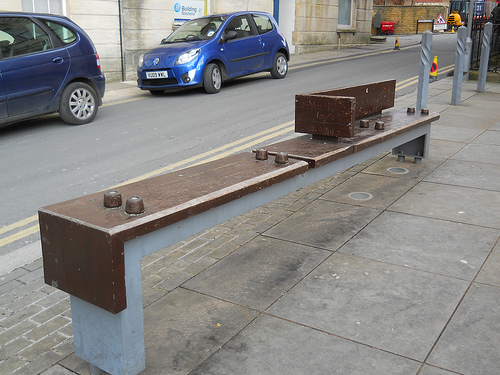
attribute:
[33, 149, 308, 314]
top —  wooden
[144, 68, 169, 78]
plate —  white and black ,  for license 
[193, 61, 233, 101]
tire — the front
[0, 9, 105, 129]
car —  small,  blue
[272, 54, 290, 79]
wheel —  the rear,  of car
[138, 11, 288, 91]
car — Blue,  small,  blue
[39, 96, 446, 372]
bench —  long,  in multiple materials, brown and white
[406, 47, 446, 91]
cone —  yellow, red, and black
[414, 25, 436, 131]
pole —  short 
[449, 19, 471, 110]
pole —  short 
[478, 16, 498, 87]
pole —  short 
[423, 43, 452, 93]
cone —  yellow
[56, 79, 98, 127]
tire — the rear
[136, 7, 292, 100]
car — Blue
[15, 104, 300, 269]
lines — parallel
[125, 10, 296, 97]
car — Blue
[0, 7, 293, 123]
cars —  two,  blue,   two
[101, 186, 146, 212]
knobs —  brown